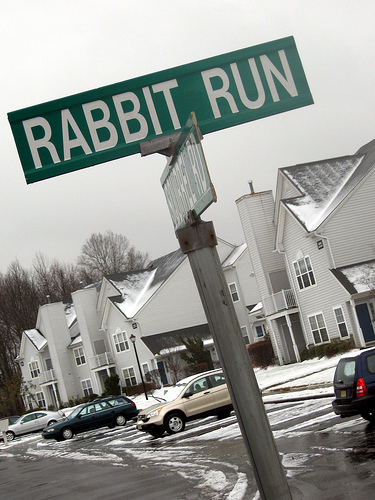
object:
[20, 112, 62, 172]
letter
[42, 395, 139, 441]
car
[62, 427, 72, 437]
tire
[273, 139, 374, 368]
building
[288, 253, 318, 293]
window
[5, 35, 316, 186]
sign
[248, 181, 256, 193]
chimney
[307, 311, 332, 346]
window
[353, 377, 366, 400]
brake light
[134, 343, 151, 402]
pole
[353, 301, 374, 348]
front door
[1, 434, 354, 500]
snow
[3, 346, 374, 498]
ground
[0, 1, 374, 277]
sky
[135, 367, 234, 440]
car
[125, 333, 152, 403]
street light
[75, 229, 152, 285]
trees